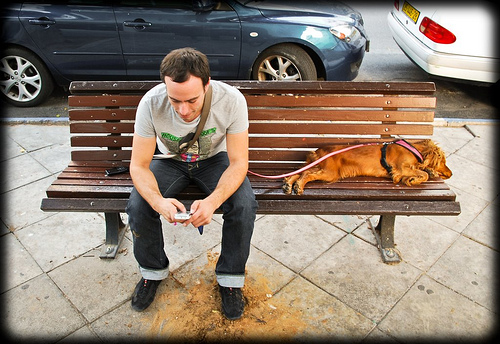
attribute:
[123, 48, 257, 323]
man — sitting, texting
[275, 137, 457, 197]
dog — sleeping, red, orange, medium, brown, lying, sitting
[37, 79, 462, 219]
bench — wood, metal, brown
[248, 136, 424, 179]
leash — pink, long, red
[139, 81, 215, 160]
bag — brown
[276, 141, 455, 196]
fur — medium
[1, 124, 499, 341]
sidewalk — concrete, tile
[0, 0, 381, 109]
car — blue, parked, blue-grey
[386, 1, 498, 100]
car — white, parked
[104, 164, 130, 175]
phone — black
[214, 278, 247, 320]
foot — resting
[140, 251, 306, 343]
dirt — reddish brown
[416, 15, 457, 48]
light — red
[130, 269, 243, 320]
sneakers — black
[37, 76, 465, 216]
slats — brown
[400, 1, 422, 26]
tag — yellow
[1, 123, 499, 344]
tile — dirty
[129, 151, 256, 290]
jeans — rolled